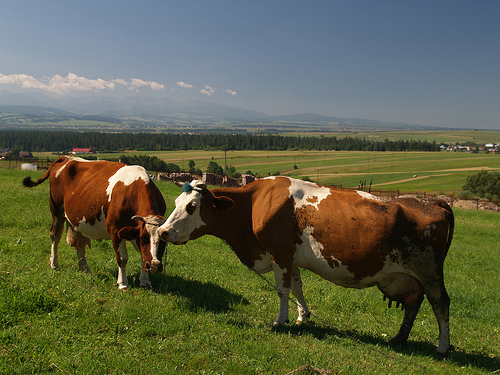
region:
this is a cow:
[156, 172, 463, 351]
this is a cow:
[12, 138, 168, 296]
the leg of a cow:
[99, 220, 133, 296]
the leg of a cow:
[275, 250, 298, 330]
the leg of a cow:
[393, 275, 421, 353]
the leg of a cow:
[431, 274, 456, 361]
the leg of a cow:
[41, 191, 63, 280]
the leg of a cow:
[78, 240, 103, 289]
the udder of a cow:
[377, 263, 420, 322]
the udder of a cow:
[49, 208, 101, 268]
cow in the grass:
[167, 176, 469, 351]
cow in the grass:
[23, 143, 170, 290]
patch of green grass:
[327, 329, 346, 355]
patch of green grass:
[102, 338, 136, 368]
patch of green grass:
[341, 319, 371, 347]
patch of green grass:
[38, 301, 70, 330]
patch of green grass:
[213, 302, 249, 334]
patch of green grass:
[43, 275, 75, 305]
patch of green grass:
[217, 288, 243, 317]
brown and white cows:
[40, 133, 457, 301]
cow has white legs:
[242, 237, 309, 347]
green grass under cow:
[160, 308, 271, 363]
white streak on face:
[124, 217, 178, 288]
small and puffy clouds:
[4, 50, 234, 120]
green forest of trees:
[1, 134, 373, 148]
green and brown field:
[262, 144, 406, 189]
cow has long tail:
[0, 157, 74, 214]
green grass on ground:
[14, 327, 52, 354]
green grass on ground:
[139, 318, 177, 355]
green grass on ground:
[191, 321, 243, 372]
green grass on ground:
[266, 334, 300, 371]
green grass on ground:
[306, 338, 365, 368]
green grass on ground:
[371, 337, 408, 366]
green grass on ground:
[6, 272, 56, 311]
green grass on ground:
[86, 262, 121, 301]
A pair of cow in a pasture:
[15, 150, 460, 357]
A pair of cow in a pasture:
[15, 150, 451, 357]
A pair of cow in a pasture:
[20, 151, 457, 356]